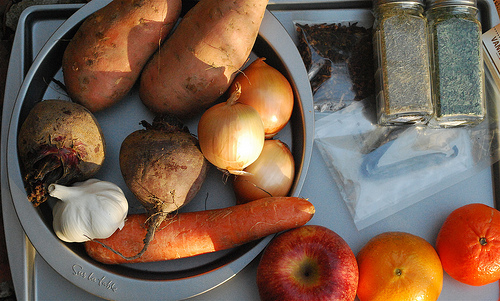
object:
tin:
[5, 0, 313, 301]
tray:
[0, 0, 499, 301]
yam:
[15, 98, 105, 206]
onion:
[227, 55, 294, 138]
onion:
[231, 137, 296, 201]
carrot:
[83, 195, 314, 263]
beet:
[83, 116, 208, 260]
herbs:
[309, 61, 330, 97]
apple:
[256, 224, 357, 301]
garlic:
[46, 177, 128, 242]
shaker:
[372, 1, 434, 126]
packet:
[312, 21, 498, 229]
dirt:
[180, 165, 188, 170]